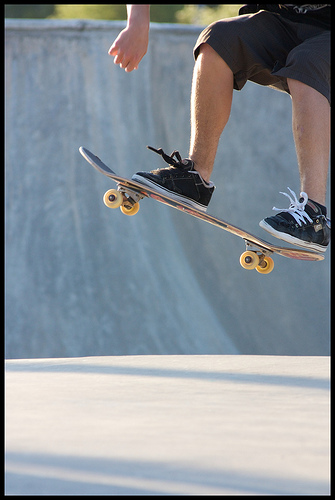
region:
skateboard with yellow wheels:
[69, 139, 329, 279]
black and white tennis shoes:
[129, 135, 333, 253]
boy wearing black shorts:
[157, 2, 332, 225]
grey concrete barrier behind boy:
[6, 16, 329, 339]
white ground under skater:
[7, 352, 331, 494]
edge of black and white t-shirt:
[232, 0, 329, 24]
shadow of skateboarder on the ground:
[8, 348, 328, 396]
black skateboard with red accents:
[73, 141, 324, 276]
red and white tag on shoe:
[301, 195, 324, 215]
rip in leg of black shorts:
[260, 49, 284, 80]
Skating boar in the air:
[62, 132, 319, 290]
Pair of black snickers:
[259, 185, 333, 252]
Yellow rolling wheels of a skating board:
[233, 243, 276, 274]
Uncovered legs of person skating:
[173, 34, 329, 169]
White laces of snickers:
[273, 186, 312, 223]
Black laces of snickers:
[143, 136, 194, 170]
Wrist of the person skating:
[96, 6, 167, 76]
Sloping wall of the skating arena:
[15, 30, 90, 335]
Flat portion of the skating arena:
[19, 364, 314, 477]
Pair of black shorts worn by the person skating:
[200, 6, 334, 103]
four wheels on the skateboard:
[109, 183, 294, 271]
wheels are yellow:
[99, 185, 146, 219]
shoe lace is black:
[119, 130, 196, 172]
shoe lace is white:
[279, 190, 316, 228]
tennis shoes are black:
[160, 158, 329, 235]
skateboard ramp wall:
[19, 5, 150, 240]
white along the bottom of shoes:
[132, 197, 209, 210]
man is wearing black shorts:
[188, 16, 331, 87]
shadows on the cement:
[88, 319, 322, 404]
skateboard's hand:
[106, 1, 174, 70]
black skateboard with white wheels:
[71, 142, 329, 280]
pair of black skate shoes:
[130, 144, 332, 260]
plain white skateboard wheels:
[95, 181, 145, 219]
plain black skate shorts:
[183, 7, 330, 113]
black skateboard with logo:
[75, 139, 325, 287]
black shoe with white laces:
[251, 183, 331, 255]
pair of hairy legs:
[178, 48, 329, 215]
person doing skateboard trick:
[38, 3, 330, 283]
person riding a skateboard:
[2, 3, 330, 284]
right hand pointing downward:
[105, 0, 154, 77]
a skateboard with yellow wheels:
[66, 160, 319, 278]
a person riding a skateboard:
[73, 19, 328, 282]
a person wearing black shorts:
[168, 10, 323, 109]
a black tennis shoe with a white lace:
[263, 81, 324, 268]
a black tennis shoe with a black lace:
[126, 128, 236, 210]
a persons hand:
[99, 3, 161, 87]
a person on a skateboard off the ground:
[62, 92, 318, 270]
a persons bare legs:
[183, 54, 314, 193]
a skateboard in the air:
[25, 152, 319, 243]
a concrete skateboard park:
[39, 60, 173, 484]